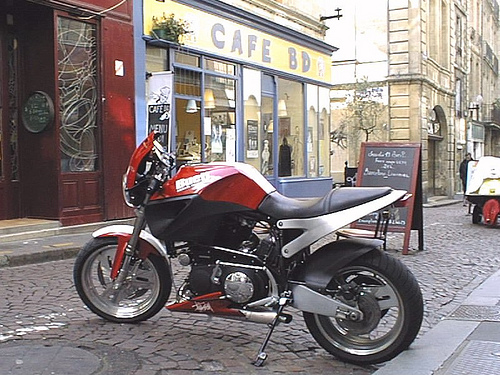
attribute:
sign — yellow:
[138, 0, 337, 90]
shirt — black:
[444, 142, 481, 180]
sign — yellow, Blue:
[353, 138, 422, 238]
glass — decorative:
[55, 8, 100, 181]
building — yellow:
[347, 8, 494, 175]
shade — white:
[183, 95, 200, 116]